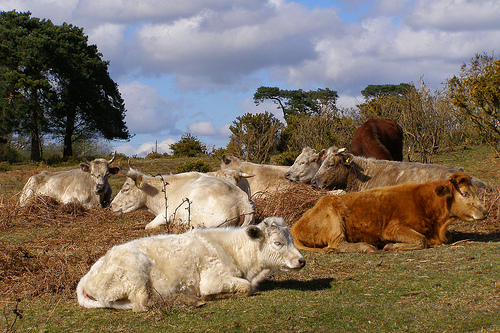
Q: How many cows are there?
A: Seven.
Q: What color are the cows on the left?
A: White.